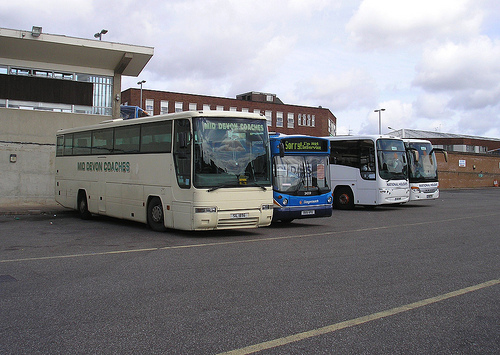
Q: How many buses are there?
A: Four.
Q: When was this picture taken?
A: Daytime.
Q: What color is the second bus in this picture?
A: Blue.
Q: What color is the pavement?
A: Grey.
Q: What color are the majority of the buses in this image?
A: White.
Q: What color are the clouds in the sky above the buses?
A: White.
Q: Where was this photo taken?
A: At the bus station.